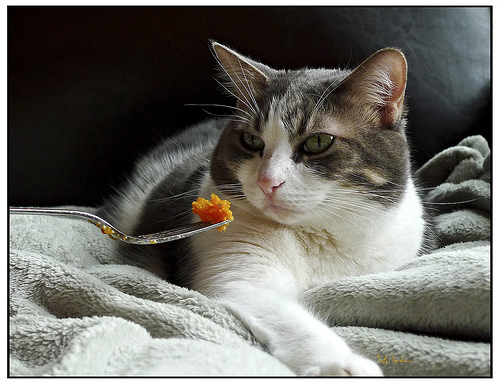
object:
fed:
[180, 171, 305, 241]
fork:
[10, 192, 237, 248]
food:
[184, 187, 239, 231]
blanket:
[12, 135, 496, 384]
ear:
[321, 40, 412, 125]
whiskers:
[295, 180, 448, 245]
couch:
[9, 10, 499, 183]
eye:
[299, 129, 336, 157]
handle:
[9, 200, 99, 228]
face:
[228, 66, 391, 228]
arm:
[201, 260, 381, 370]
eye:
[231, 130, 267, 164]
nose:
[253, 174, 285, 203]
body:
[106, 113, 428, 380]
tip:
[187, 215, 233, 236]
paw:
[295, 349, 387, 379]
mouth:
[259, 196, 301, 223]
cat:
[106, 42, 427, 382]